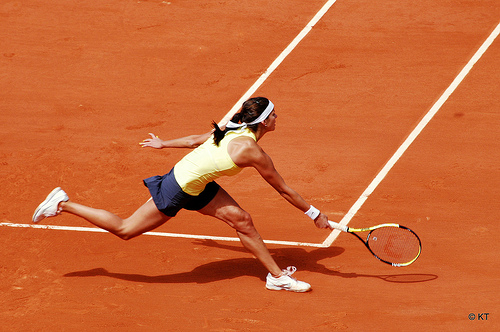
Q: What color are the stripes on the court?
A: White.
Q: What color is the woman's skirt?
A: Blue.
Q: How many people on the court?
A: One.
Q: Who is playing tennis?
A: A woman.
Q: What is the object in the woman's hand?
A: Tennis racket.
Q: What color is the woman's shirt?
A: Yellow.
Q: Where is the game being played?
A: Tennis court.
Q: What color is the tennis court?
A: Brown and white.